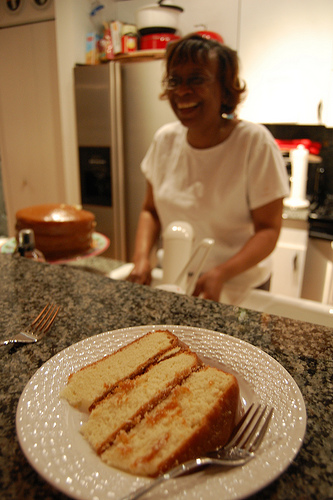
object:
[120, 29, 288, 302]
woman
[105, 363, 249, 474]
food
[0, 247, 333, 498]
table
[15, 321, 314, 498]
plate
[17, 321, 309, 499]
design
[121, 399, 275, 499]
fork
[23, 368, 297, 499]
light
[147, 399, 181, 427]
crumbs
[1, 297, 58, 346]
fork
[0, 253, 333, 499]
counter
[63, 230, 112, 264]
cake plate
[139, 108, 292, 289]
shirt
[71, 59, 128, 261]
refrigerator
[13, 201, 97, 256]
cake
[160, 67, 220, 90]
eyeglasses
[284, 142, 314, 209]
roll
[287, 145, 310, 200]
towels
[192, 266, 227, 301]
hand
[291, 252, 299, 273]
handle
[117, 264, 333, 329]
kitchen sink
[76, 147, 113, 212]
water dispenser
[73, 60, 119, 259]
door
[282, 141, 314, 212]
rack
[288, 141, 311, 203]
paper towel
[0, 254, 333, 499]
countertop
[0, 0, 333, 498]
kitchen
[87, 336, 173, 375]
icing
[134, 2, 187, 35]
crock pot